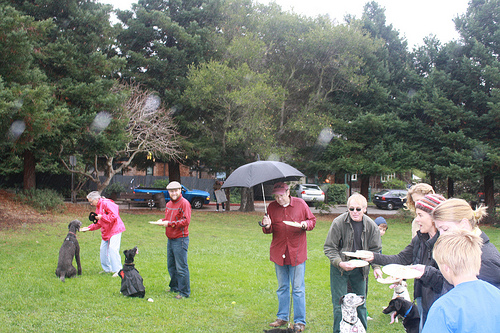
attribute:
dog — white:
[335, 288, 372, 331]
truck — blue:
[126, 177, 213, 217]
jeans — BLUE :
[267, 254, 312, 321]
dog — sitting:
[51, 214, 81, 286]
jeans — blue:
[278, 252, 358, 312]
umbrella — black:
[207, 133, 301, 212]